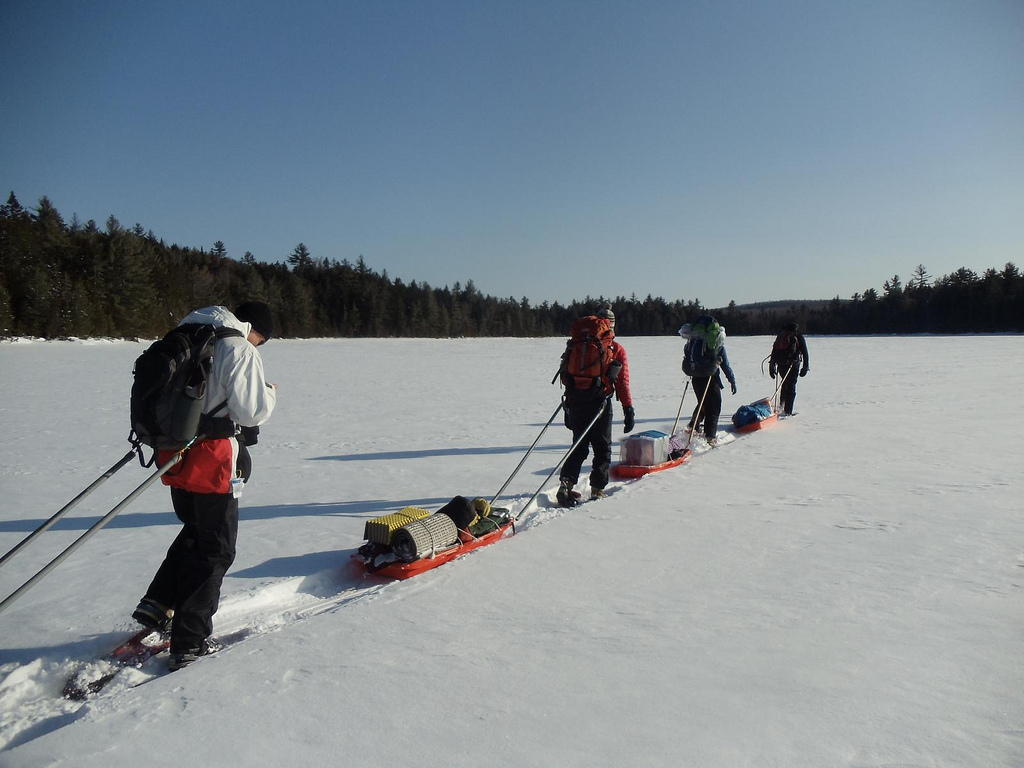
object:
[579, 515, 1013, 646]
snow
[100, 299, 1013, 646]
people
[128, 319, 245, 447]
backpack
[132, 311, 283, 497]
person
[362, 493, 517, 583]
package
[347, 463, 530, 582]
cart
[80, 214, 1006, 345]
trees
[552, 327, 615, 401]
backpack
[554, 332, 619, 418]
back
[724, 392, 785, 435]
bag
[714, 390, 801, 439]
surface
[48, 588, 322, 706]
skis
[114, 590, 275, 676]
feet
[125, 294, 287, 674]
person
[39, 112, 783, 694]
picture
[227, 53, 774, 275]
sky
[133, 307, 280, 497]
jacket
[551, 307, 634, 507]
man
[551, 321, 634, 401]
jacket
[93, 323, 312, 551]
man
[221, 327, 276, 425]
arm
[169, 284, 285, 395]
hood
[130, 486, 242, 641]
leg